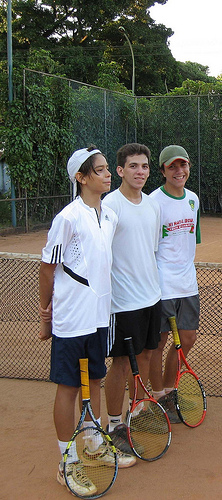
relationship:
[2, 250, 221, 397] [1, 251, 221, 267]
net has top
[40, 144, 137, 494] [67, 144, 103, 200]
boy with hat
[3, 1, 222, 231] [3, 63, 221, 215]
forest behind fence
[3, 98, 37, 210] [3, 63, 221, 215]
ivy on fence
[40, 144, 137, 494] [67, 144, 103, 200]
boy has hat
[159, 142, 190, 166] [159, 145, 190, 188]
hat on head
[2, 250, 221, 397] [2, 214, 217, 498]
net on court